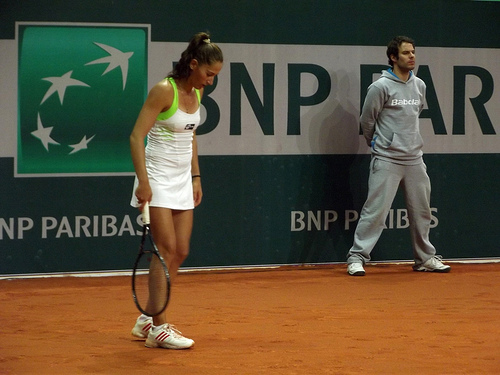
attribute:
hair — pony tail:
[168, 33, 223, 70]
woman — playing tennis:
[71, 27, 259, 358]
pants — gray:
[343, 155, 433, 270]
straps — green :
[157, 74, 207, 129]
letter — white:
[1, 208, 122, 247]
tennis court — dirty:
[1, 0, 498, 373]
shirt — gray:
[362, 77, 431, 150]